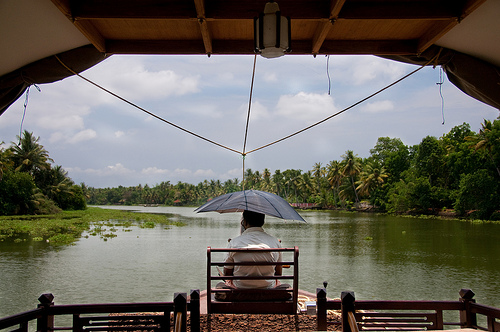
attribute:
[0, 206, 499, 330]
water — calm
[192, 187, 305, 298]
man — with umbrella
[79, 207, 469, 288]
water — green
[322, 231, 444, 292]
water — green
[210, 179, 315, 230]
umbrella — black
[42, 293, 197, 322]
railings — brown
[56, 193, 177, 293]
water — green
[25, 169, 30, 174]
leaf — green 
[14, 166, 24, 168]
leaf — green 